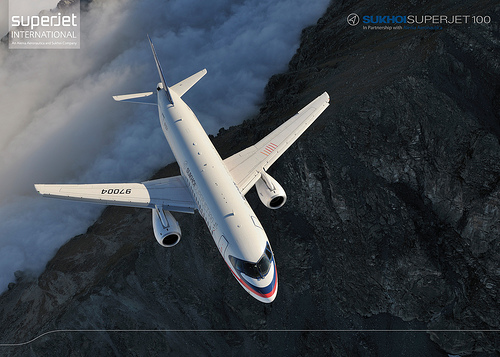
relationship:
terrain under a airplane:
[1, 11, 485, 351] [35, 32, 333, 302]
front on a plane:
[227, 261, 279, 302] [15, 38, 331, 310]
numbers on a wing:
[98, 184, 140, 195] [35, 167, 186, 212]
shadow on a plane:
[169, 166, 239, 238] [118, 80, 395, 297]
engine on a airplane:
[149, 200, 184, 248] [35, 32, 333, 302]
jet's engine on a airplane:
[256, 171, 287, 208] [35, 32, 333, 302]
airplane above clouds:
[35, 32, 333, 302] [216, 30, 284, 83]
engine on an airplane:
[149, 200, 184, 249] [32, 34, 331, 304]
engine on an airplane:
[252, 169, 291, 211] [32, 34, 331, 304]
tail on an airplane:
[110, 36, 211, 108] [146, 64, 258, 311]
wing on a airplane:
[34, 174, 197, 210] [32, 34, 331, 304]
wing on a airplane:
[225, 91, 333, 176] [32, 34, 331, 304]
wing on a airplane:
[168, 67, 207, 96] [32, 34, 331, 304]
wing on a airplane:
[113, 87, 158, 105] [32, 34, 331, 304]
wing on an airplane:
[225, 82, 333, 176] [32, 34, 331, 304]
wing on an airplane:
[29, 170, 197, 210] [32, 34, 331, 304]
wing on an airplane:
[168, 67, 207, 96] [32, 34, 331, 304]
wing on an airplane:
[109, 87, 159, 105] [32, 34, 331, 304]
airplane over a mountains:
[26, 30, 380, 295] [1, 3, 483, 352]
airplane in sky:
[35, 32, 333, 302] [6, 20, 498, 355]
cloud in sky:
[0, 0, 336, 290] [6, 20, 498, 355]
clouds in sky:
[0, 4, 319, 287] [6, 20, 498, 355]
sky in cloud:
[266, 0, 348, 55] [0, 0, 336, 290]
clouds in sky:
[16, 90, 111, 165] [20, 29, 405, 317]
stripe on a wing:
[266, 143, 276, 152] [216, 87, 337, 197]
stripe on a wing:
[264, 144, 275, 152] [216, 87, 337, 197]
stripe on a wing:
[263, 145, 273, 154] [216, 87, 337, 197]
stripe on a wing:
[258, 149, 269, 156] [216, 87, 337, 197]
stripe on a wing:
[264, 145, 276, 155] [216, 87, 337, 197]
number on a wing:
[101, 186, 133, 197] [36, 172, 199, 212]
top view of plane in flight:
[20, 114, 359, 196] [49, 116, 378, 357]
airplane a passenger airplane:
[35, 32, 333, 302] [35, 32, 333, 302]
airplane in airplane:
[35, 32, 333, 302] [35, 32, 333, 302]